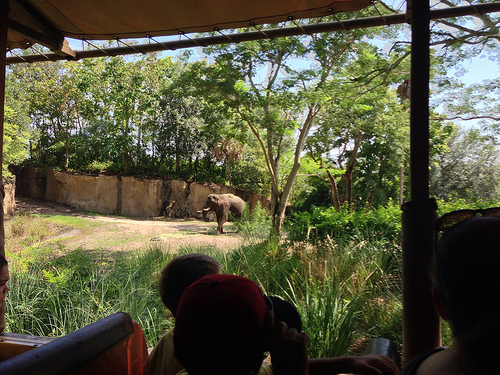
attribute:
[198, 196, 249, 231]
elephant — grey, walking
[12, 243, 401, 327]
grass — green, tall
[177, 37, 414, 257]
tree — tall, small, large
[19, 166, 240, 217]
stones — small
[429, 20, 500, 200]
sky — blue, in background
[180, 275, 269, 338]
cap — red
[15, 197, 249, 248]
dirt — brown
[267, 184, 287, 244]
trunk — brown